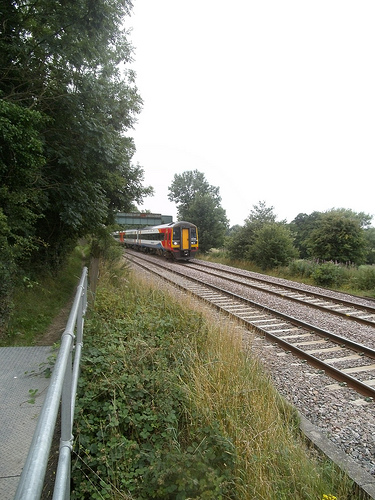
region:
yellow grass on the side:
[200, 363, 235, 390]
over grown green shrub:
[90, 344, 160, 435]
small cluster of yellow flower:
[313, 488, 338, 498]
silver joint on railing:
[54, 434, 84, 454]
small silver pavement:
[8, 346, 34, 407]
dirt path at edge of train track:
[32, 264, 83, 346]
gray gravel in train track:
[277, 374, 324, 401]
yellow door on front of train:
[181, 224, 197, 249]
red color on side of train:
[147, 221, 179, 250]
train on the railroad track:
[134, 211, 221, 267]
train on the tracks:
[104, 219, 210, 262]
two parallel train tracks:
[123, 241, 374, 464]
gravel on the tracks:
[123, 247, 374, 457]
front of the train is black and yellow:
[171, 223, 196, 252]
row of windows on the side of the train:
[137, 232, 166, 241]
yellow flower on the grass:
[317, 487, 342, 498]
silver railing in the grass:
[11, 261, 122, 498]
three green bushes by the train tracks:
[284, 252, 374, 293]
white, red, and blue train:
[107, 216, 201, 259]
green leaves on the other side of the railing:
[16, 344, 63, 416]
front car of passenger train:
[170, 225, 204, 252]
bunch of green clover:
[111, 370, 156, 409]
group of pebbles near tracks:
[315, 409, 373, 465]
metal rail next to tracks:
[59, 390, 92, 450]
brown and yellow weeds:
[223, 359, 270, 434]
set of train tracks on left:
[231, 291, 263, 349]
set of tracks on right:
[291, 281, 341, 322]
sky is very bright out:
[195, 97, 297, 175]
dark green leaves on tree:
[59, 157, 110, 234]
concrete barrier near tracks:
[301, 418, 342, 480]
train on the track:
[167, 223, 206, 264]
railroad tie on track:
[305, 345, 344, 351]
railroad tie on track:
[325, 353, 362, 363]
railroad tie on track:
[345, 364, 374, 372]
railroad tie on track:
[289, 338, 325, 347]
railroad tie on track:
[263, 324, 305, 330]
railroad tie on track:
[251, 317, 277, 322]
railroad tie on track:
[235, 309, 256, 314]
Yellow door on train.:
[179, 228, 192, 248]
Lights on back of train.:
[171, 238, 199, 251]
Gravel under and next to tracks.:
[215, 264, 328, 398]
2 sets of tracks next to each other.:
[233, 269, 357, 375]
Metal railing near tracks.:
[27, 335, 96, 451]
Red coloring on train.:
[156, 231, 169, 255]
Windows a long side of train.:
[134, 229, 166, 244]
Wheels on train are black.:
[134, 243, 171, 261]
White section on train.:
[137, 224, 157, 248]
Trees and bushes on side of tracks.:
[247, 218, 351, 269]